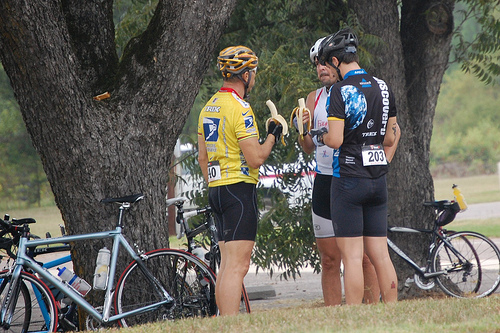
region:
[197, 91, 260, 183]
The yellow shirt the man is wearing.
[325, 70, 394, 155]
The black shirt the man is wearing.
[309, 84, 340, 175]
The white shirt the man is wearing.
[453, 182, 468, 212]
The yellow sports bottle on the bike.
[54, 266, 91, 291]
The sports bottle with the blue top.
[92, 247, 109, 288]
The sports bottle with the white top.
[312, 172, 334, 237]
The black and white biker shorts the man is wearing.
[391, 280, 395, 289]
The tattoo on the back of the man's leg.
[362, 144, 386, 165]
The sticker number 203 on the man's shirt.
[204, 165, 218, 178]
The number 40 on the sticker of the man's yellow shirt.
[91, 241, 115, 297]
water bottle attached to a bike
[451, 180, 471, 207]
water bottle on back of the bike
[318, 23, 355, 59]
man wearing a black helmet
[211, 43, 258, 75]
man wearing a yellow helmet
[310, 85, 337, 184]
man wearing a white shirt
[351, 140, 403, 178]
number tag on back of the shirt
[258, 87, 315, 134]
men eating bananas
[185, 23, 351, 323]
two people eating bananas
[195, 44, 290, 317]
Man in a yellow shirt eating a banana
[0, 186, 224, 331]
Bikes resting against a tree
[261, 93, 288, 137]
Open banana in man's hand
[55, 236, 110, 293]
Two water bottles on the bike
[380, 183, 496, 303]
Bike resting against a tree